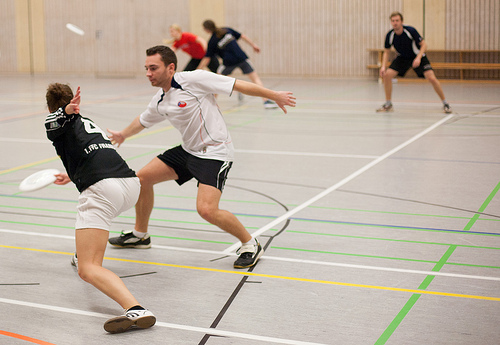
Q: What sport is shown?
A: Frisbee.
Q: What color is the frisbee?
A: White.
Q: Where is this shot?
A: Rec center courts.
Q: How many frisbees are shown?
A: 2.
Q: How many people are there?
A: 5.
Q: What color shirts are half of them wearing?
A: Black.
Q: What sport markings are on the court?
A: Basketball.